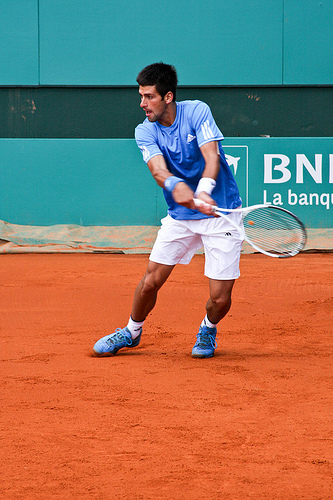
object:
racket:
[192, 198, 306, 258]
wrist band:
[163, 175, 184, 191]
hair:
[135, 62, 177, 102]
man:
[91, 63, 244, 358]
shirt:
[133, 99, 241, 218]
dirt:
[0, 252, 331, 498]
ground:
[0, 223, 332, 498]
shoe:
[93, 325, 141, 356]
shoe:
[191, 323, 217, 357]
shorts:
[147, 203, 245, 282]